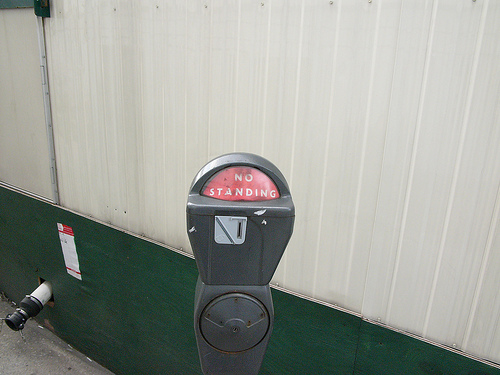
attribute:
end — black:
[3, 294, 40, 332]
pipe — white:
[30, 281, 51, 308]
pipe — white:
[4, 276, 55, 331]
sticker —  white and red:
[53, 219, 81, 284]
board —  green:
[0, 189, 497, 373]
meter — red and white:
[183, 150, 297, 374]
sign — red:
[198, 164, 281, 204]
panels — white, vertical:
[56, 15, 495, 325]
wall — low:
[270, 0, 497, 374]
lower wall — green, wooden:
[0, 185, 200, 373]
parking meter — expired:
[190, 147, 296, 358]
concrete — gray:
[5, 303, 127, 373]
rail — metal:
[33, 22, 65, 206]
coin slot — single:
[213, 214, 246, 246]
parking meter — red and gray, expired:
[184, 152, 295, 372]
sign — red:
[192, 149, 287, 213]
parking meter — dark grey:
[146, 148, 306, 355]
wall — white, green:
[23, 116, 170, 336]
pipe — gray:
[25, 7, 70, 209]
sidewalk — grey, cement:
[11, 340, 63, 370]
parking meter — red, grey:
[163, 119, 308, 364]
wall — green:
[29, 33, 498, 314]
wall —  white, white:
[7, 15, 499, 372]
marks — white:
[245, 207, 276, 229]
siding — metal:
[1, 0, 496, 364]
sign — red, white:
[54, 222, 79, 284]